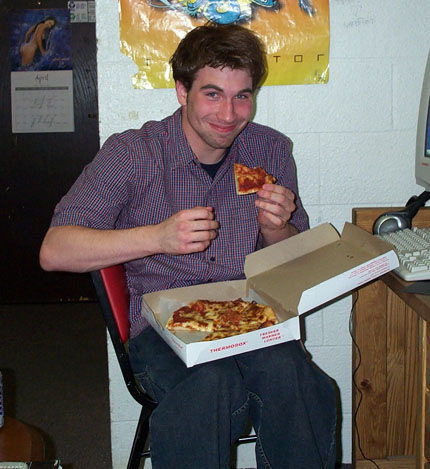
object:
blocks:
[317, 129, 429, 206]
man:
[39, 16, 341, 469]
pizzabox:
[138, 221, 401, 371]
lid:
[240, 220, 398, 316]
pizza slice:
[232, 161, 278, 196]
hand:
[254, 183, 298, 231]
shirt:
[49, 111, 312, 342]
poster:
[119, 0, 330, 88]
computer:
[370, 54, 430, 282]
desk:
[350, 204, 430, 469]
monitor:
[414, 52, 430, 191]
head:
[167, 16, 265, 149]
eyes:
[206, 90, 221, 98]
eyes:
[237, 94, 249, 100]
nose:
[215, 92, 236, 123]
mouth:
[206, 122, 237, 132]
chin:
[209, 133, 236, 149]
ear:
[175, 79, 187, 106]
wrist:
[137, 224, 159, 259]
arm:
[38, 132, 157, 276]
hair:
[169, 15, 263, 98]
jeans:
[124, 324, 342, 469]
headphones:
[372, 190, 430, 236]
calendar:
[8, 7, 74, 134]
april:
[34, 73, 49, 86]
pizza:
[161, 297, 282, 346]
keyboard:
[372, 226, 429, 282]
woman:
[18, 16, 57, 69]